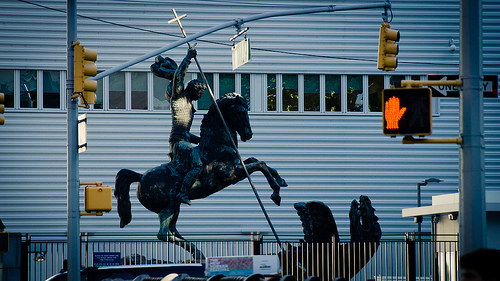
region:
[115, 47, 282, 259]
statue of man on horse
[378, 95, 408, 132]
glowing red hand on sign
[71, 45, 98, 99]
side of yellow traffic lights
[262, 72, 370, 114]
row of rectangle windows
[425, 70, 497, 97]
one way sign behind pole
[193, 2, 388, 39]
curved horizontal gray pole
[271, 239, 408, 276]
poles of metal gate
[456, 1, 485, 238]
vertical gray metal pole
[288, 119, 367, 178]
ridges on gray wall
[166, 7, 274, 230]
cross on long pole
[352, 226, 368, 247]
part of a fence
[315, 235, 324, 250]
edge of a fence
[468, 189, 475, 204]
part of a pole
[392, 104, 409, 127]
part of a post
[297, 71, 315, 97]
part of a window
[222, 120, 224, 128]
part of an horse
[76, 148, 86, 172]
part of a pole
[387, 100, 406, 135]
part of a light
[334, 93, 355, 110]
edge of a window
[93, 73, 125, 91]
part of a traffic light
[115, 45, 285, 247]
A horse sculpture in the photo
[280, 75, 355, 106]
Windows in the photo.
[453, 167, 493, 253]
A metallic pole in the photo.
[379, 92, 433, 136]
A hand signal on the traffic lights.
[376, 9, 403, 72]
Traffic lights hanging in the photo.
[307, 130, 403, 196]
A blue wall in the photo.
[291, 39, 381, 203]
A building in the photo.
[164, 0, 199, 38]
A cross in the photo.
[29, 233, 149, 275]
Metallic barriers in the photo.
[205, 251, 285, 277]
Signage with writings in the photo.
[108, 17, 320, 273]
a statue of a man holding a cros while riding a horse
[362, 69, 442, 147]
a do not walk sign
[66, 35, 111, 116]
a stop light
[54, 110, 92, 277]
a tall stop light pole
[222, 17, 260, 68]
a road sign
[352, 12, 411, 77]
a hanging stop light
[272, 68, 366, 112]
some windows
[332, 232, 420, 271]
a small metal fence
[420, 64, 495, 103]
a one way street sign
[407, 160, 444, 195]
a small light pole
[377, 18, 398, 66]
yellow colored stop light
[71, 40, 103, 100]
yellow colored stop light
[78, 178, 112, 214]
yellow colored walk light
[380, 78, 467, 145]
yellow colored walk light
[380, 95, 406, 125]
orange light in shape of hand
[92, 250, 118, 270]
blue colored metal sign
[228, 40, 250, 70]
silver colored metal sign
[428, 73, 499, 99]
black and white street sign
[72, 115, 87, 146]
silver colored street sign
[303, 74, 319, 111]
large clear building window